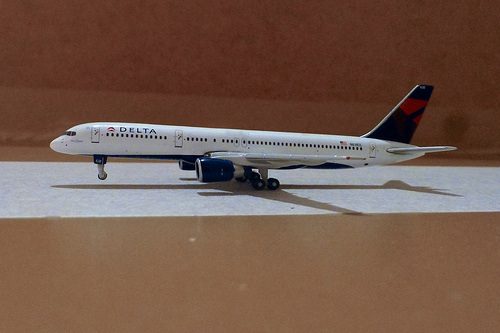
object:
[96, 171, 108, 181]
wheel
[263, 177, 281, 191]
wheel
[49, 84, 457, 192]
airplanes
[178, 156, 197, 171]
right engine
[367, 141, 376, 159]
exit door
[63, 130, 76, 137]
windows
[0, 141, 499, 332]
ground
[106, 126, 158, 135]
delta logo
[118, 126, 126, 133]
word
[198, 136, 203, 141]
window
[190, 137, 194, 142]
window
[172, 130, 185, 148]
door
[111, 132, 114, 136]
window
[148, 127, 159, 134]
writing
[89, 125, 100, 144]
exit door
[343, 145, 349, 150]
windows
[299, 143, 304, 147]
window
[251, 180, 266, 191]
wheels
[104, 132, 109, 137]
window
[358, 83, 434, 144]
tail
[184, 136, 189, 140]
window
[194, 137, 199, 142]
window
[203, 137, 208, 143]
window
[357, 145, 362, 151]
windows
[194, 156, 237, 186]
engine